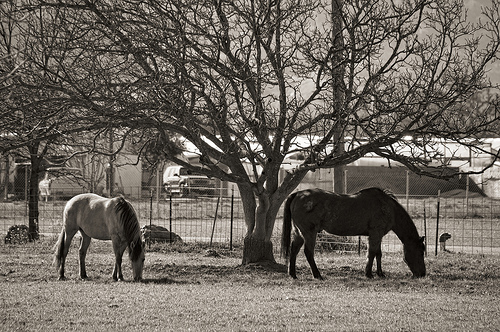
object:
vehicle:
[160, 164, 215, 199]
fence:
[0, 180, 488, 250]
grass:
[257, 285, 487, 321]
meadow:
[6, 187, 469, 330]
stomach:
[326, 207, 369, 236]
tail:
[279, 196, 295, 266]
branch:
[264, 43, 287, 136]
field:
[0, 230, 498, 328]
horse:
[279, 183, 428, 281]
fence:
[0, 190, 499, 257]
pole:
[330, 0, 349, 198]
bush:
[5, 224, 35, 244]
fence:
[10, 182, 499, 262]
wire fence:
[0, 185, 499, 260]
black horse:
[283, 185, 429, 286]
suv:
[162, 162, 220, 196]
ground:
[282, 0, 412, 82]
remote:
[277, 177, 435, 281]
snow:
[178, 134, 499, 197]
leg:
[364, 232, 381, 281]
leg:
[373, 238, 385, 279]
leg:
[300, 224, 325, 281]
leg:
[288, 233, 306, 281]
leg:
[108, 241, 125, 279]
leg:
[109, 244, 127, 284]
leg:
[76, 230, 93, 282]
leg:
[54, 229, 71, 279]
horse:
[50, 193, 147, 281]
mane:
[117, 197, 144, 247]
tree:
[1, 0, 497, 268]